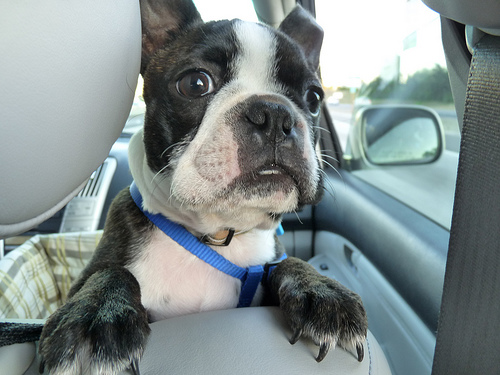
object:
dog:
[34, 1, 374, 374]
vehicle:
[1, 2, 496, 372]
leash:
[124, 178, 290, 308]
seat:
[1, 302, 392, 375]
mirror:
[344, 104, 447, 172]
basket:
[1, 229, 107, 342]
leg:
[33, 265, 152, 374]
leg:
[269, 255, 371, 362]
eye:
[167, 63, 222, 103]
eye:
[299, 80, 326, 120]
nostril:
[242, 109, 272, 135]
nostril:
[280, 112, 296, 138]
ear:
[138, 0, 204, 78]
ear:
[275, 3, 325, 76]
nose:
[236, 90, 299, 150]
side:
[293, 4, 499, 298]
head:
[129, 0, 330, 237]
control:
[56, 197, 102, 235]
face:
[144, 21, 328, 224]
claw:
[290, 327, 304, 345]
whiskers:
[159, 141, 191, 160]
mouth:
[228, 153, 310, 212]